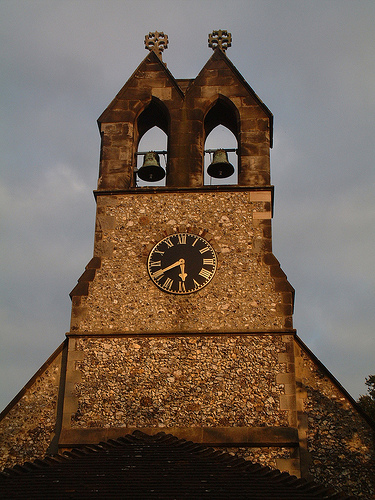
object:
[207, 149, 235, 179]
bell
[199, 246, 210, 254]
metal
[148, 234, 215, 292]
face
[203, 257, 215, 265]
numeral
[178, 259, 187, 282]
golden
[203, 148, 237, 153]
pole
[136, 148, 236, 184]
two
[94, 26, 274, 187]
top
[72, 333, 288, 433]
wall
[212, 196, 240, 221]
colors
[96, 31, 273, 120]
roof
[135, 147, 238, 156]
beam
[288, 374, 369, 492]
shadows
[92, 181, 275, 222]
shingles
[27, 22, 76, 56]
cloudy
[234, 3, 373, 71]
sky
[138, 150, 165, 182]
bell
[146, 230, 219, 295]
clock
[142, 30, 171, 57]
decor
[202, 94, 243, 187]
arched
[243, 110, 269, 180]
brick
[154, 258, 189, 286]
5:40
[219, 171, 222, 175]
shaft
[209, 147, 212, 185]
rope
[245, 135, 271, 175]
block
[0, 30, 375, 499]
belfry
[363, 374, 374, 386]
leaf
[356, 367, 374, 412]
tree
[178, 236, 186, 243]
numerals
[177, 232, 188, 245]
twelve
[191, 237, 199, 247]
one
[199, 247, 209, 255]
two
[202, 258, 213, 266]
three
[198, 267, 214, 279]
four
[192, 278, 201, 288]
five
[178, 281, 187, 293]
six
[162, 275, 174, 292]
seven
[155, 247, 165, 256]
ten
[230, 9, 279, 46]
cloud